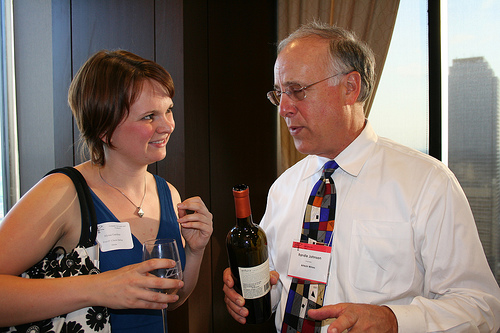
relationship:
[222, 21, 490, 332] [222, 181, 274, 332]
man holding bottle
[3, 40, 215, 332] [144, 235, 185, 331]
woman holding glass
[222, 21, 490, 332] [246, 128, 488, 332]
man wearing shirt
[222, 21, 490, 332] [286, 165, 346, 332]
man wearing tie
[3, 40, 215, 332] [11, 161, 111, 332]
woman carrying purse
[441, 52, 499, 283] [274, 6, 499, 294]
building in window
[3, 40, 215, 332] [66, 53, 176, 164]
woman has hair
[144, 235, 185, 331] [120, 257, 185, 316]
glass in hand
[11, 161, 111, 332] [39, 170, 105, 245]
purse on shoulder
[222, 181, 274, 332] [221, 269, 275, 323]
bottle in hand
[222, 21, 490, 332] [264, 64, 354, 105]
man wearing glasses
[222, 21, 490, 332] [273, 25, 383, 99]
man has hair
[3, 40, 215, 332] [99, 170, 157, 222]
woman wearing necklace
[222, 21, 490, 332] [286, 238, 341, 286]
man wearing nametag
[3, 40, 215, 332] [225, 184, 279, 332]
woman drinking wine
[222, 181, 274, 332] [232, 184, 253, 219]
bottle has neck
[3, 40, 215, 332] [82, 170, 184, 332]
woman wearing dress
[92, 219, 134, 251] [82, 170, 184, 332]
sticker on dress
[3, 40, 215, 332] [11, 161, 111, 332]
woman holding purse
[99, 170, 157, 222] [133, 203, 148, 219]
necklace has charm